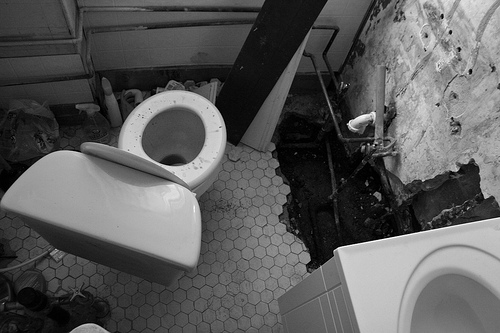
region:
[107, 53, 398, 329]
a toilet that is in the bathroom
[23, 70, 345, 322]
a white bathroom toilet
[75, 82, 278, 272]
a toilet that is white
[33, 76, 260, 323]
a bathroom toilet that is white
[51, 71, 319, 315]
a toilet with lid up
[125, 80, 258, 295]
a toilet with seat down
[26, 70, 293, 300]
a white toilet with lid up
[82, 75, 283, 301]
a white toilet with seat down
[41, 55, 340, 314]
a bathroom toilet with lid up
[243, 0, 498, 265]
this bathroom has seen better days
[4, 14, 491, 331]
bathroom might be undergoing renovation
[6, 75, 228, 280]
toilet sitting in the middle of a bathroom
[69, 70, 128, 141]
cleaning materials on the floor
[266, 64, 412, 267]
tile has been torn out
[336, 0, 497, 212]
plaster on the wall has been removed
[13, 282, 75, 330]
can of something on the floor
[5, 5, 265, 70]
plumbing pipes run along the wall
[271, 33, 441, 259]
no toilet connected to the plumbing pipes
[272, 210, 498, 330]
sink is surprisingly clean during renovation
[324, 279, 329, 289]
edge of a sink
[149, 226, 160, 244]
part of a tank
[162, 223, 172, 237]
edge of a tank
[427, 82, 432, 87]
part of a wall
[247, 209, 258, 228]
edge of a wall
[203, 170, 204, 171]
edge of a toilet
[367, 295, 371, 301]
edge of a sink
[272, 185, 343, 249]
A crooked toilet floor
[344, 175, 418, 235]
A crooked toilet floor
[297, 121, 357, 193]
A crooked toilet floor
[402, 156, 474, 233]
A crooked toilet wall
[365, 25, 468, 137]
A crooked toilet wall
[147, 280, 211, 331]
A white toilet floor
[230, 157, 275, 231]
A white toilet floor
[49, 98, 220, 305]
A white dirty toilet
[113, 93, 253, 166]
white part of the toilet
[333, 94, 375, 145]
a top to the wall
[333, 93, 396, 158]
a tap on side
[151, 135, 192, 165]
whole in the toilet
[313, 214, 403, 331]
a part of basin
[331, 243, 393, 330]
a part of sink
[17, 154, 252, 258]
a box to hold water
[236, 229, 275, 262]
design on the floor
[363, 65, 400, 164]
hammer on the pipe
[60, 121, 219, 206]
white lid on the toilet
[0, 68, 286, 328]
toilet bowl in the middle of floor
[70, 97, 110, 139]
spray bottle on the floor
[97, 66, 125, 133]
spray bottle on the floor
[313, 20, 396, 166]
pipes in the wall